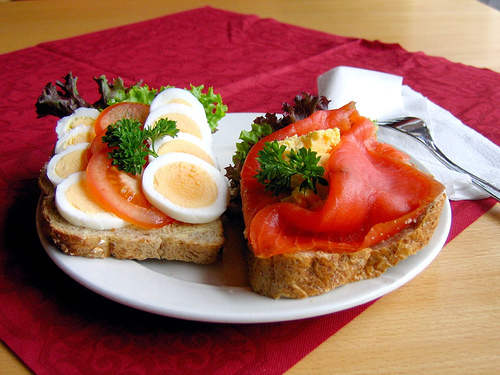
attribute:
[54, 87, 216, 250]
sandwhich — brown, halved, two peices, red, covered, round, white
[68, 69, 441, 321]
plate — white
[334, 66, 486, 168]
napkin — white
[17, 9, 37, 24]
table — wooden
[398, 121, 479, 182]
fork — silver